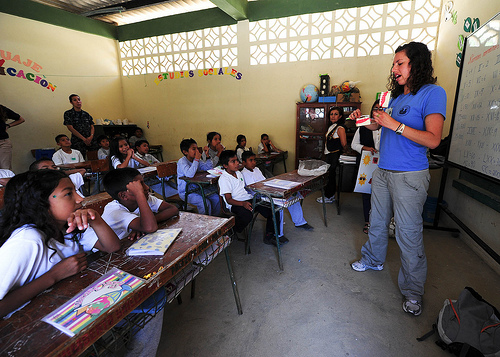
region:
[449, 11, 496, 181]
White board with writing on it.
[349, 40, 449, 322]
Girl giving speech.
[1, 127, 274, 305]
Students sitting at desks.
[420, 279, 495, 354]
Gray and black backpack on floor.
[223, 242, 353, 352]
Concrete flooring in classroom.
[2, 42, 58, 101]
Colorful writing on wall.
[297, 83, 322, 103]
Blue round globe on cabinet.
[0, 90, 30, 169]
Teacher standing in back of class.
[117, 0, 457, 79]
Shadow of windows on wall.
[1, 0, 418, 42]
Painted green border on wall.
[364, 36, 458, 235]
a woman teaching students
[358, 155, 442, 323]
a woman wearing gray athletic pants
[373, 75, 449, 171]
a woman wearing a blue shirt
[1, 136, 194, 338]
students sitting at tables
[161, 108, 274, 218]
students listening to the teacher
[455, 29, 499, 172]
a marker board for the classroom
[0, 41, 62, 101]
decorations for the classroom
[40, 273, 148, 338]
a students colorful handbook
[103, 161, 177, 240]
a boy rests his head on his hand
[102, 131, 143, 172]
a girl smiles in class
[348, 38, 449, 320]
Teacher standing in front of the class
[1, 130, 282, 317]
Children at desks sitting in the classroom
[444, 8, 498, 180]
Whiteboard on the wall behind the teacher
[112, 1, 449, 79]
Windows on the rear wall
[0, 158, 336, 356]
Two desks in the front row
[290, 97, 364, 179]
Wooden cabinet on the rear wall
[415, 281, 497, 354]
Backpack on the floor next to the teacher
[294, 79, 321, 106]
Globe sitting on top of the cabinet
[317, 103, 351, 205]
Woman standing in front of the cabinet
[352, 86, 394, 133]
Red and white cards the teacher is holding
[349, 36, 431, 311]
speaker in a classroom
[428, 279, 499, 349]
bag on the ground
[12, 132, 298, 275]
children listening to presentation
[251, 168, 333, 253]
desk for children to sit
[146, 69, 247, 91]
letters on the wall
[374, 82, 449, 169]
top on presentation speaker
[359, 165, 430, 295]
pants on presentation speaker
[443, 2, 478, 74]
decorations on the wall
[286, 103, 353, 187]
cabinets with materials in them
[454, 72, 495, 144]
writing on a board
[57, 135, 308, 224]
students sitting in a classroom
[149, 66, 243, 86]
'social studies' spelled out in spanish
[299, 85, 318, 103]
a globe on a shelf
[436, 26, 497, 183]
a white board behind the teacher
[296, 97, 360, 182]
a cabinet under the globe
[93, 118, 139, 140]
a shelf in the back of the room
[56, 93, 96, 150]
a person wearing a bracelet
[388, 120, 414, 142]
a watch on the woman's wrist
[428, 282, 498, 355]
a backpack on the floor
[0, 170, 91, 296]
a girl with a braid in her hair